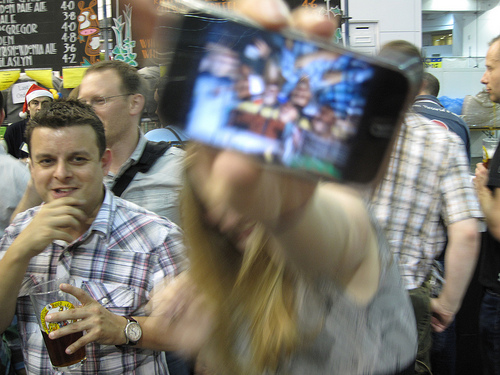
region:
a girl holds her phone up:
[132, 5, 427, 374]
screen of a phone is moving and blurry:
[156, 10, 411, 185]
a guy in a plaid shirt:
[1, 99, 191, 372]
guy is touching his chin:
[20, 99, 115, 253]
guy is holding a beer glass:
[4, 98, 188, 373]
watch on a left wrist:
[113, 308, 146, 355]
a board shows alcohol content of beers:
[0, 0, 82, 70]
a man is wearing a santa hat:
[4, 80, 59, 156]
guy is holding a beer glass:
[465, 32, 499, 371]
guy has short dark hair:
[0, 95, 191, 373]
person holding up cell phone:
[128, 5, 450, 372]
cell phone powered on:
[128, 0, 417, 203]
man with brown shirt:
[22, 96, 117, 175]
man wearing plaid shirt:
[1, 151, 199, 372]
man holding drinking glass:
[24, 272, 108, 369]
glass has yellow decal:
[21, 260, 103, 370]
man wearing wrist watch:
[111, 298, 151, 353]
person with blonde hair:
[160, 130, 332, 364]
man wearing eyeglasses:
[74, 73, 126, 114]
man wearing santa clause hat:
[11, 55, 66, 150]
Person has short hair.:
[24, 98, 145, 160]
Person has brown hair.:
[37, 103, 102, 139]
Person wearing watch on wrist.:
[120, 310, 160, 373]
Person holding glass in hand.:
[33, 282, 111, 371]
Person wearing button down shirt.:
[37, 250, 99, 292]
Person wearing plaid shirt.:
[76, 248, 126, 303]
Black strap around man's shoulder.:
[120, 136, 168, 183]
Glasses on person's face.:
[76, 87, 139, 125]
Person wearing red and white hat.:
[18, 83, 50, 112]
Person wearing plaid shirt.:
[399, 158, 428, 213]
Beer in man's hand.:
[26, 275, 94, 370]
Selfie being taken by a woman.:
[145, 5, 415, 193]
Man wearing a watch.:
[120, 306, 147, 346]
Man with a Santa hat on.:
[15, 75, 51, 121]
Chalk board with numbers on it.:
[0, 0, 106, 65]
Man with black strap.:
[107, 132, 185, 196]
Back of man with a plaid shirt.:
[364, 111, 486, 293]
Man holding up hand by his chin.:
[2, 193, 86, 343]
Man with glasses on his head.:
[70, 88, 147, 110]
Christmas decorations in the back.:
[72, 0, 145, 65]